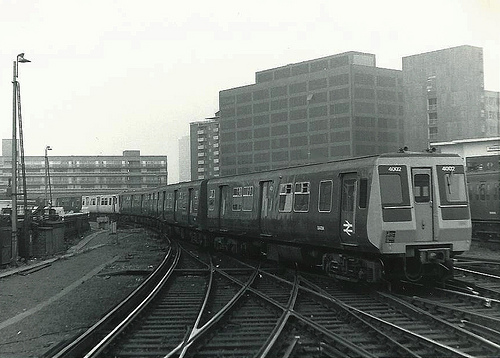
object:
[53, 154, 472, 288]
train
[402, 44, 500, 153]
building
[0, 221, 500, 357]
train yard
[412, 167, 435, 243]
door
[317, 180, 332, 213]
window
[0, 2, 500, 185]
sky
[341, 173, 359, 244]
backdoor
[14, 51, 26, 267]
pole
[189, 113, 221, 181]
building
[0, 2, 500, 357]
picture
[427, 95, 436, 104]
window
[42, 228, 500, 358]
track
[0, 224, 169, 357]
gravel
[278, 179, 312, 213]
passengers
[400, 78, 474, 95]
multi stories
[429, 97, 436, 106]
porches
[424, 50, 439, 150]
row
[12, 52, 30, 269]
steet light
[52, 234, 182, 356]
rails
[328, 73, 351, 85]
window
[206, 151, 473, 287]
car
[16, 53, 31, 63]
instrument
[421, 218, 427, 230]
symbol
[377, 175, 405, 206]
window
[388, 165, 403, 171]
numbers